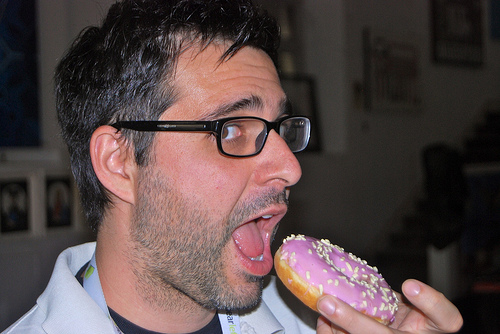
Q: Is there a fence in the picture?
A: No, there are no fences.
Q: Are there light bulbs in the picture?
A: No, there are no light bulbs.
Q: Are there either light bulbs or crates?
A: No, there are no light bulbs or crates.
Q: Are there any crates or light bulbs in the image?
A: No, there are no light bulbs or crates.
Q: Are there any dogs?
A: No, there are no dogs.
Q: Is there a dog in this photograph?
A: No, there are no dogs.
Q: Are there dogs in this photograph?
A: No, there are no dogs.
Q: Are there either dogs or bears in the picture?
A: No, there are no dogs or bears.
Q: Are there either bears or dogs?
A: No, there are no dogs or bears.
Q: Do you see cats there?
A: No, there are no cats.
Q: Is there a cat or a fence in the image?
A: No, there are no cats or fences.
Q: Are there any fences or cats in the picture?
A: No, there are no cats or fences.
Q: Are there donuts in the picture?
A: Yes, there is a donut.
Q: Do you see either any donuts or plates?
A: Yes, there is a donut.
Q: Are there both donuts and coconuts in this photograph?
A: No, there is a donut but no coconuts.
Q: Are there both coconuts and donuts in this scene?
A: No, there is a donut but no coconuts.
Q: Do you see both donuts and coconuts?
A: No, there is a donut but no coconuts.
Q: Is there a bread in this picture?
A: No, there is no breads.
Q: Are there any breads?
A: No, there are no breads.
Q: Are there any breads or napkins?
A: No, there are no breads or napkins.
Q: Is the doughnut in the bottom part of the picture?
A: Yes, the doughnut is in the bottom of the image.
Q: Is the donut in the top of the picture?
A: No, the donut is in the bottom of the image.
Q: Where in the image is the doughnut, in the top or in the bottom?
A: The doughnut is in the bottom of the image.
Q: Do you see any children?
A: No, there are no children.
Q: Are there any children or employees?
A: No, there are no children or employees.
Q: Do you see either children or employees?
A: No, there are no children or employees.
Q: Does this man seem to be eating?
A: Yes, the man is eating.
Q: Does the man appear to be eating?
A: Yes, the man is eating.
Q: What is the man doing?
A: The man is eating.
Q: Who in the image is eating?
A: The man is eating.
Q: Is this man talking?
A: No, the man is eating.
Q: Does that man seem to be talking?
A: No, the man is eating.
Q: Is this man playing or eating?
A: The man is eating.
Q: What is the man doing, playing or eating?
A: The man is eating.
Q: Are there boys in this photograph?
A: No, there are no boys.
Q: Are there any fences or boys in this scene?
A: No, there are no boys or fences.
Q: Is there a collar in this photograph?
A: Yes, there is a collar.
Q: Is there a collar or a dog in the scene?
A: Yes, there is a collar.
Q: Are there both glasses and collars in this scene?
A: Yes, there are both a collar and glasses.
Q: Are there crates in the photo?
A: No, there are no crates.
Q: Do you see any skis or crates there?
A: No, there are no crates or skis.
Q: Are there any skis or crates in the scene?
A: No, there are no crates or skis.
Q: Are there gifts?
A: No, there are no gifts.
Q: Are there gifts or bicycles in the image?
A: No, there are no gifts or bicycles.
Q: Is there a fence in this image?
A: No, there are no fences.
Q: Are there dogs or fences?
A: No, there are no fences or dogs.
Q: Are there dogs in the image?
A: No, there are no dogs.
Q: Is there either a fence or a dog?
A: No, there are no dogs or fences.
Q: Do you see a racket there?
A: No, there are no rackets.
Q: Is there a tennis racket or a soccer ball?
A: No, there are no rackets or soccer balls.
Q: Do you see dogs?
A: No, there are no dogs.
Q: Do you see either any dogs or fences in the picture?
A: No, there are no dogs or fences.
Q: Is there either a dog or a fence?
A: No, there are no dogs or fences.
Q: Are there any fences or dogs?
A: No, there are no dogs or fences.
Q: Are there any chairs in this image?
A: No, there are no chairs.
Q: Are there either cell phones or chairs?
A: No, there are no chairs or cell phones.